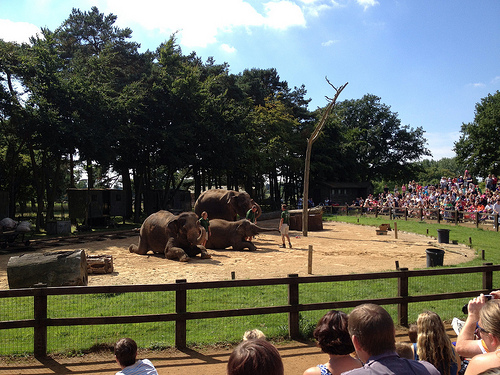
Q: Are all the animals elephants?
A: Yes, all the animals are elephants.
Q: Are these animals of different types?
A: No, all the animals are elephants.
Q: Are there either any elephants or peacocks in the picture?
A: Yes, there is an elephant.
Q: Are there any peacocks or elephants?
A: Yes, there is an elephant.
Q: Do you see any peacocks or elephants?
A: Yes, there is an elephant.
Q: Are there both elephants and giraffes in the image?
A: No, there is an elephant but no giraffes.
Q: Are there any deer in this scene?
A: No, there are no deer.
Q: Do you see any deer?
A: No, there are no deer.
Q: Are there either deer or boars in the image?
A: No, there are no deer or boars.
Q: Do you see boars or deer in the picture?
A: No, there are no deer or boars.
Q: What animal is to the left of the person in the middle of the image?
A: The animal is an elephant.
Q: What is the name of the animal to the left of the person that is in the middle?
A: The animal is an elephant.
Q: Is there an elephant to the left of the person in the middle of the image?
A: Yes, there is an elephant to the left of the person.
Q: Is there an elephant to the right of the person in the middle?
A: No, the elephant is to the left of the person.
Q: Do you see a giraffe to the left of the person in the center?
A: No, there is an elephant to the left of the person.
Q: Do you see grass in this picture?
A: Yes, there is grass.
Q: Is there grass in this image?
A: Yes, there is grass.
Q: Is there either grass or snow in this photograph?
A: Yes, there is grass.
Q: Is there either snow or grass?
A: Yes, there is grass.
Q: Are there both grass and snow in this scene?
A: No, there is grass but no snow.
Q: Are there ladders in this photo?
A: No, there are no ladders.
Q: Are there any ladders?
A: No, there are no ladders.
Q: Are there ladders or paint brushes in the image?
A: No, there are no ladders or paint brushes.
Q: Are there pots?
A: No, there are no pots.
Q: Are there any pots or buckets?
A: No, there are no pots or buckets.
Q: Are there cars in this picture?
A: No, there are no cars.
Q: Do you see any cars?
A: No, there are no cars.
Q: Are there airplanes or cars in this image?
A: No, there are no cars or airplanes.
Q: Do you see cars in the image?
A: No, there are no cars.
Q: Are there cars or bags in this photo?
A: No, there are no cars or bags.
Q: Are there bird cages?
A: No, there are no bird cages.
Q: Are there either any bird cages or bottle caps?
A: No, there are no bird cages or bottle caps.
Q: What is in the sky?
A: The clouds are in the sky.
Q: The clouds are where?
A: The clouds are in the sky.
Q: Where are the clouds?
A: The clouds are in the sky.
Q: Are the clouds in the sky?
A: Yes, the clouds are in the sky.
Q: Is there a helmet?
A: No, there are no helmets.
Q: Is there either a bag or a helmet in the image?
A: No, there are no helmets or bags.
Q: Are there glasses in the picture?
A: No, there are no glasses.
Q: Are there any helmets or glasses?
A: No, there are no glasses or helmets.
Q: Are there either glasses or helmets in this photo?
A: No, there are no glasses or helmets.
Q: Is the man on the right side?
A: Yes, the man is on the right of the image.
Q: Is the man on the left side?
A: No, the man is on the right of the image.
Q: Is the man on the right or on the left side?
A: The man is on the right of the image.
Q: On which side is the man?
A: The man is on the right of the image.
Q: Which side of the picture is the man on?
A: The man is on the right of the image.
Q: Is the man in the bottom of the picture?
A: Yes, the man is in the bottom of the image.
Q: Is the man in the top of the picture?
A: No, the man is in the bottom of the image.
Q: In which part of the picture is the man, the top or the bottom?
A: The man is in the bottom of the image.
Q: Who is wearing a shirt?
A: The man is wearing a shirt.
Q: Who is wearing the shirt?
A: The man is wearing a shirt.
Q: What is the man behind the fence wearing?
A: The man is wearing a shirt.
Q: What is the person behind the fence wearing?
A: The man is wearing a shirt.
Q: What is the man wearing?
A: The man is wearing a shirt.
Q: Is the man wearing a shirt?
A: Yes, the man is wearing a shirt.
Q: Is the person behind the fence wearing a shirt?
A: Yes, the man is wearing a shirt.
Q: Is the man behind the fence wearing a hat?
A: No, the man is wearing a shirt.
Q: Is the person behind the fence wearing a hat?
A: No, the man is wearing a shirt.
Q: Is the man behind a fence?
A: Yes, the man is behind a fence.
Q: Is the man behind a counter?
A: No, the man is behind a fence.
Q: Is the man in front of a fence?
A: No, the man is behind a fence.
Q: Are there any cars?
A: No, there are no cars.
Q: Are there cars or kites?
A: No, there are no cars or kites.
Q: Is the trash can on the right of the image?
A: Yes, the trash can is on the right of the image.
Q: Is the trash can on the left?
A: No, the trash can is on the right of the image.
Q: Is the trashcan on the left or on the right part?
A: The trashcan is on the right of the image.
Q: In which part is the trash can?
A: The trash can is on the right of the image.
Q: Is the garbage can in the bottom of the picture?
A: Yes, the garbage can is in the bottom of the image.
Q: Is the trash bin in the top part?
A: No, the trash bin is in the bottom of the image.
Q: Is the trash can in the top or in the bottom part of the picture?
A: The trash can is in the bottom of the image.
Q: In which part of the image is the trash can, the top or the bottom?
A: The trash can is in the bottom of the image.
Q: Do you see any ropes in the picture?
A: No, there are no ropes.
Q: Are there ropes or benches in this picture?
A: No, there are no ropes or benches.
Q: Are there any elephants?
A: Yes, there is an elephant.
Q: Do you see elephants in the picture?
A: Yes, there is an elephant.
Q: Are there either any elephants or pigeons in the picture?
A: Yes, there is an elephant.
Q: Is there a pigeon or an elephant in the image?
A: Yes, there is an elephant.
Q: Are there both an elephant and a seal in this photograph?
A: No, there is an elephant but no seals.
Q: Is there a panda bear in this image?
A: No, there are no panda bears.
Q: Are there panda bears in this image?
A: No, there are no panda bears.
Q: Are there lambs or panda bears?
A: No, there are no panda bears or lambs.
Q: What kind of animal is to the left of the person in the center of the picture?
A: The animal is an elephant.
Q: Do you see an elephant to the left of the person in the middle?
A: Yes, there is an elephant to the left of the person.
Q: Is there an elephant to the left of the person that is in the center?
A: Yes, there is an elephant to the left of the person.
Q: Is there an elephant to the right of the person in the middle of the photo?
A: No, the elephant is to the left of the person.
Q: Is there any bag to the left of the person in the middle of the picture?
A: No, there is an elephant to the left of the person.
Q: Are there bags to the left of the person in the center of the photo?
A: No, there is an elephant to the left of the person.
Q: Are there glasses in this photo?
A: No, there are no glasses.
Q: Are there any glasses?
A: No, there are no glasses.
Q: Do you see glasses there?
A: No, there are no glasses.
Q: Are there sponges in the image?
A: No, there are no sponges.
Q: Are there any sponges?
A: No, there are no sponges.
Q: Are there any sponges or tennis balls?
A: No, there are no sponges or tennis balls.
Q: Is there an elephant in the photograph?
A: Yes, there is an elephant.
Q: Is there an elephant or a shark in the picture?
A: Yes, there is an elephant.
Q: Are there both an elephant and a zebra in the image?
A: No, there is an elephant but no zebras.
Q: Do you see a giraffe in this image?
A: No, there are no giraffes.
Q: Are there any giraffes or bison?
A: No, there are no giraffes or bison.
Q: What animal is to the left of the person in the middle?
A: The animal is an elephant.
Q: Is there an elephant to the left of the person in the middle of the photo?
A: Yes, there is an elephant to the left of the person.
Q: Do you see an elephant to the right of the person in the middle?
A: No, the elephant is to the left of the person.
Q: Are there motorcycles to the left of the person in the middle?
A: No, there is an elephant to the left of the person.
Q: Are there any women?
A: Yes, there is a woman.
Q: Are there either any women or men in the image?
A: Yes, there is a woman.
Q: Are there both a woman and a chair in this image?
A: No, there is a woman but no chairs.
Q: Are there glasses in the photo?
A: No, there are no glasses.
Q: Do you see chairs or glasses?
A: No, there are no glasses or chairs.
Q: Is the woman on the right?
A: Yes, the woman is on the right of the image.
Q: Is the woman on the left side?
A: No, the woman is on the right of the image.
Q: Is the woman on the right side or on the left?
A: The woman is on the right of the image.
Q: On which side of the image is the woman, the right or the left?
A: The woman is on the right of the image.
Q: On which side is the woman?
A: The woman is on the right of the image.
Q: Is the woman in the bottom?
A: Yes, the woman is in the bottom of the image.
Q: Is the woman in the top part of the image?
A: No, the woman is in the bottom of the image.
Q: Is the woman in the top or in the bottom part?
A: The woman is in the bottom of the image.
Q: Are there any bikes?
A: No, there are no bikes.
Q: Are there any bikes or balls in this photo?
A: No, there are no bikes or balls.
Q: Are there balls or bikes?
A: No, there are no bikes or balls.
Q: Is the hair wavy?
A: Yes, the hair is wavy.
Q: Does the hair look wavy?
A: Yes, the hair is wavy.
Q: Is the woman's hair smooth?
A: No, the hair is wavy.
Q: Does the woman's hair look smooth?
A: No, the hair is wavy.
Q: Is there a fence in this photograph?
A: Yes, there is a fence.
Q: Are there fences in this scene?
A: Yes, there is a fence.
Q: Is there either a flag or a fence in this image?
A: Yes, there is a fence.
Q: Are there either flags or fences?
A: Yes, there is a fence.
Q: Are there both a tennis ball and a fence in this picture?
A: No, there is a fence but no tennis balls.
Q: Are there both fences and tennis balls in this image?
A: No, there is a fence but no tennis balls.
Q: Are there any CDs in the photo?
A: No, there are no cds.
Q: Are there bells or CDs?
A: No, there are no CDs or bells.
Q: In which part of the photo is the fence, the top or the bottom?
A: The fence is in the bottom of the image.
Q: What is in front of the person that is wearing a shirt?
A: The fence is in front of the man.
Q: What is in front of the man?
A: The fence is in front of the man.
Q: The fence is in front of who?
A: The fence is in front of the man.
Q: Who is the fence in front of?
A: The fence is in front of the man.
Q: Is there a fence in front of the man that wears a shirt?
A: Yes, there is a fence in front of the man.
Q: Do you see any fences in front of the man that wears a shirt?
A: Yes, there is a fence in front of the man.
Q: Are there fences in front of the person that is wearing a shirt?
A: Yes, there is a fence in front of the man.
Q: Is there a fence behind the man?
A: No, the fence is in front of the man.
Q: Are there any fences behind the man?
A: No, the fence is in front of the man.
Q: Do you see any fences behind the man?
A: No, the fence is in front of the man.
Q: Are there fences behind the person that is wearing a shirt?
A: No, the fence is in front of the man.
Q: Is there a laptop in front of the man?
A: No, there is a fence in front of the man.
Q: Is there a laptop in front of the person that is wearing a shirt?
A: No, there is a fence in front of the man.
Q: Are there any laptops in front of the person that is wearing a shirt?
A: No, there is a fence in front of the man.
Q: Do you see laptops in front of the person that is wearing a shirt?
A: No, there is a fence in front of the man.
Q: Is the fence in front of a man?
A: Yes, the fence is in front of a man.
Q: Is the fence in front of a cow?
A: No, the fence is in front of a man.